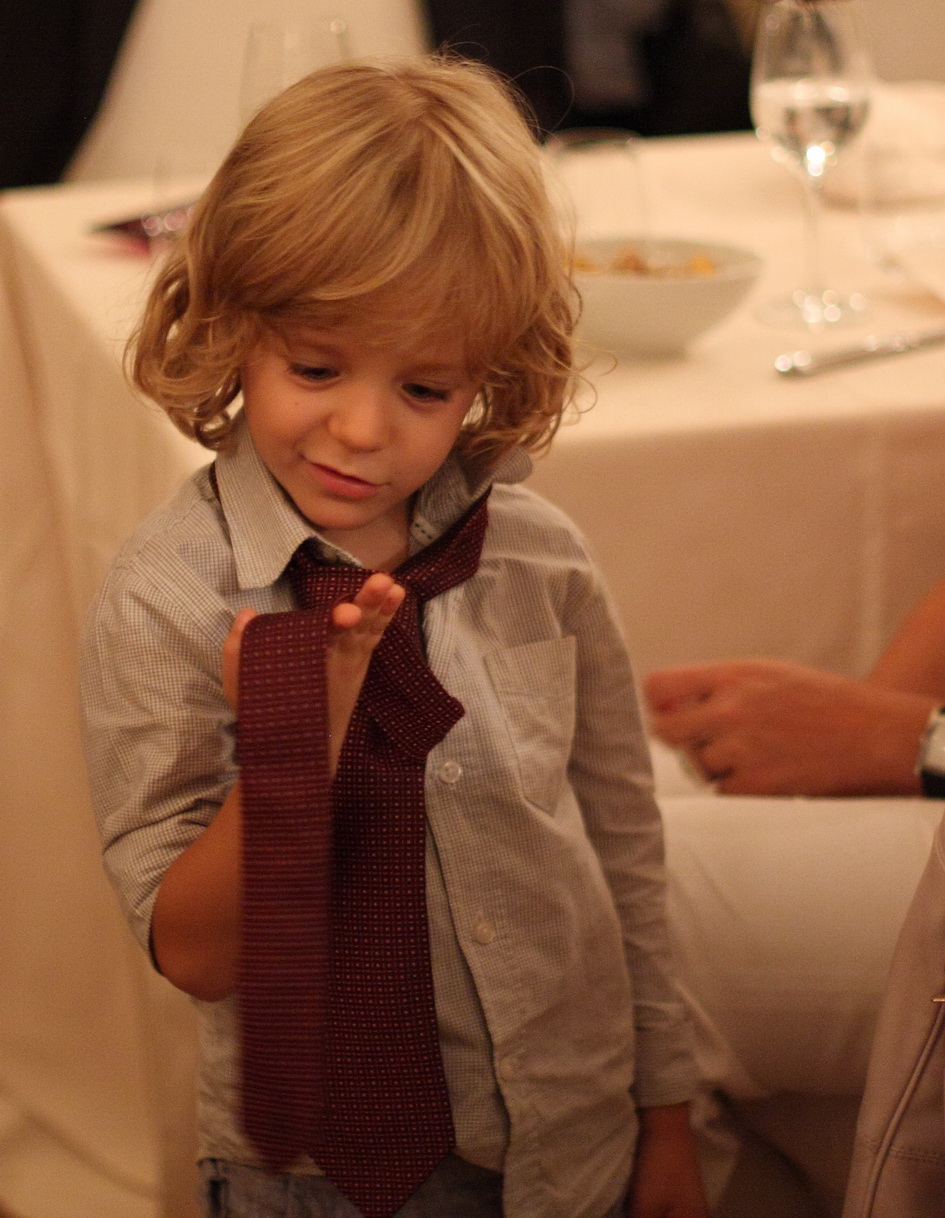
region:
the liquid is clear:
[789, 115, 836, 152]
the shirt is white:
[470, 628, 548, 713]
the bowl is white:
[594, 282, 657, 319]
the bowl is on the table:
[616, 336, 684, 369]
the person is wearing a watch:
[913, 687, 944, 803]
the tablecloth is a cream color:
[639, 454, 728, 529]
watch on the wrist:
[918, 697, 943, 800]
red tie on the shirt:
[232, 622, 340, 1162]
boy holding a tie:
[120, 50, 680, 1202]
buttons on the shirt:
[433, 755, 508, 962]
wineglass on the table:
[742, 1, 872, 342]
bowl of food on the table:
[562, 216, 757, 382]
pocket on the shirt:
[483, 632, 586, 834]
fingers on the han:
[329, 570, 407, 673]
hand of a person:
[634, 648, 859, 808]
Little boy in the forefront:
[82, 57, 721, 1213]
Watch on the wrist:
[909, 691, 942, 797]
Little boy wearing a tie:
[75, 39, 718, 1216]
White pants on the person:
[608, 551, 942, 1211]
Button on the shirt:
[430, 756, 466, 789]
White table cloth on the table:
[1, 127, 941, 1216]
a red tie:
[337, 1027, 418, 1155]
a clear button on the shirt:
[436, 751, 469, 782]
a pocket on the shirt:
[483, 643, 591, 788]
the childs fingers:
[337, 594, 381, 627]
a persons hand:
[683, 672, 842, 808]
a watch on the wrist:
[913, 711, 942, 787]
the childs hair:
[341, 137, 485, 285]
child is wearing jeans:
[240, 1181, 306, 1209]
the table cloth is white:
[680, 390, 779, 444]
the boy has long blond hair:
[151, 50, 570, 518]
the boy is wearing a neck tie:
[145, 47, 575, 1163]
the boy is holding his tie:
[156, 58, 588, 716]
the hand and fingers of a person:
[654, 622, 874, 806]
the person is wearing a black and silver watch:
[665, 643, 943, 806]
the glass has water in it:
[754, 12, 874, 325]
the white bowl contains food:
[562, 224, 755, 354]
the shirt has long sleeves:
[93, 458, 727, 1134]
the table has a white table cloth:
[6, 117, 942, 666]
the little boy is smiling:
[168, 213, 512, 541]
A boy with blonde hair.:
[65, 47, 750, 1178]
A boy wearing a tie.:
[101, 58, 781, 1212]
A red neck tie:
[231, 517, 501, 1213]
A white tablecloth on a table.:
[5, 106, 940, 1086]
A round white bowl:
[561, 233, 752, 363]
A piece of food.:
[687, 253, 709, 284]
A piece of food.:
[618, 252, 635, 270]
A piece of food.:
[643, 263, 665, 275]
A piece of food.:
[694, 247, 716, 278]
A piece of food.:
[602, 248, 637, 273]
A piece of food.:
[637, 260, 681, 276]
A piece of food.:
[555, 244, 583, 269]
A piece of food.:
[593, 264, 613, 281]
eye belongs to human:
[291, 357, 345, 384]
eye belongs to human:
[392, 376, 455, 409]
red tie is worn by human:
[236, 487, 499, 1216]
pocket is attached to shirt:
[485, 629, 588, 823]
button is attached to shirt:
[438, 757, 466, 786]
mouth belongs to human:
[300, 457, 386, 504]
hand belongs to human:
[223, 564, 410, 766]